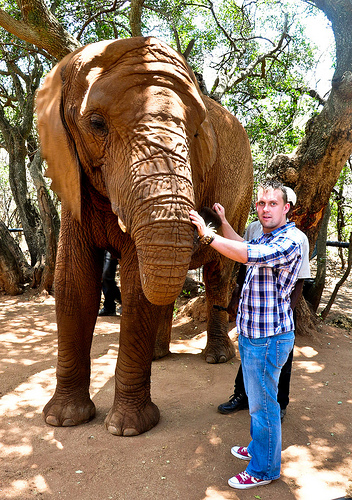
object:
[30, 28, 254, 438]
elephant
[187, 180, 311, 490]
man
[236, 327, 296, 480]
pants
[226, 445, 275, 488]
shoes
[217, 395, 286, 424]
shoes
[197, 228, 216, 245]
bracelet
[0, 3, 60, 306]
trees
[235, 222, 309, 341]
shirt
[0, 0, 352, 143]
sky